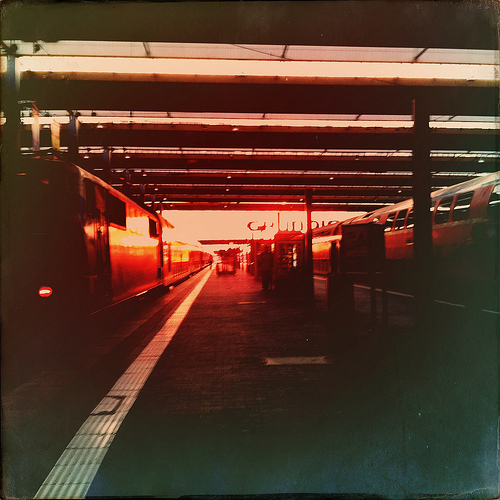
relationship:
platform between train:
[92, 267, 439, 475] [254, 176, 484, 301]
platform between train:
[92, 267, 439, 475] [38, 143, 218, 322]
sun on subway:
[121, 217, 197, 251] [0, 154, 213, 342]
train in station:
[253, 197, 498, 304] [0, 0, 499, 497]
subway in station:
[0, 154, 213, 342] [4, 8, 498, 498]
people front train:
[242, 235, 398, 315] [315, 177, 498, 300]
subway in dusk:
[0, 154, 213, 342] [115, 199, 342, 299]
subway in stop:
[0, 154, 213, 342] [10, 143, 497, 461]